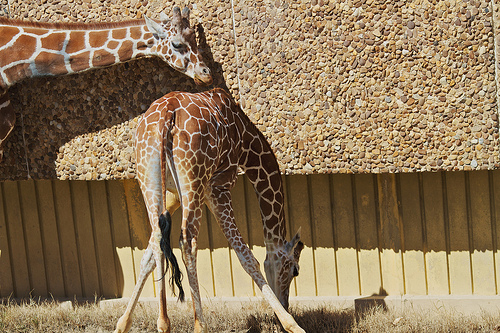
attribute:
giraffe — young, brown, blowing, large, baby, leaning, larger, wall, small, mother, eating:
[65, 67, 368, 333]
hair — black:
[131, 217, 203, 293]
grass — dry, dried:
[15, 288, 88, 327]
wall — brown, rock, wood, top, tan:
[278, 1, 481, 152]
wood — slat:
[317, 179, 392, 292]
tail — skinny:
[139, 130, 192, 228]